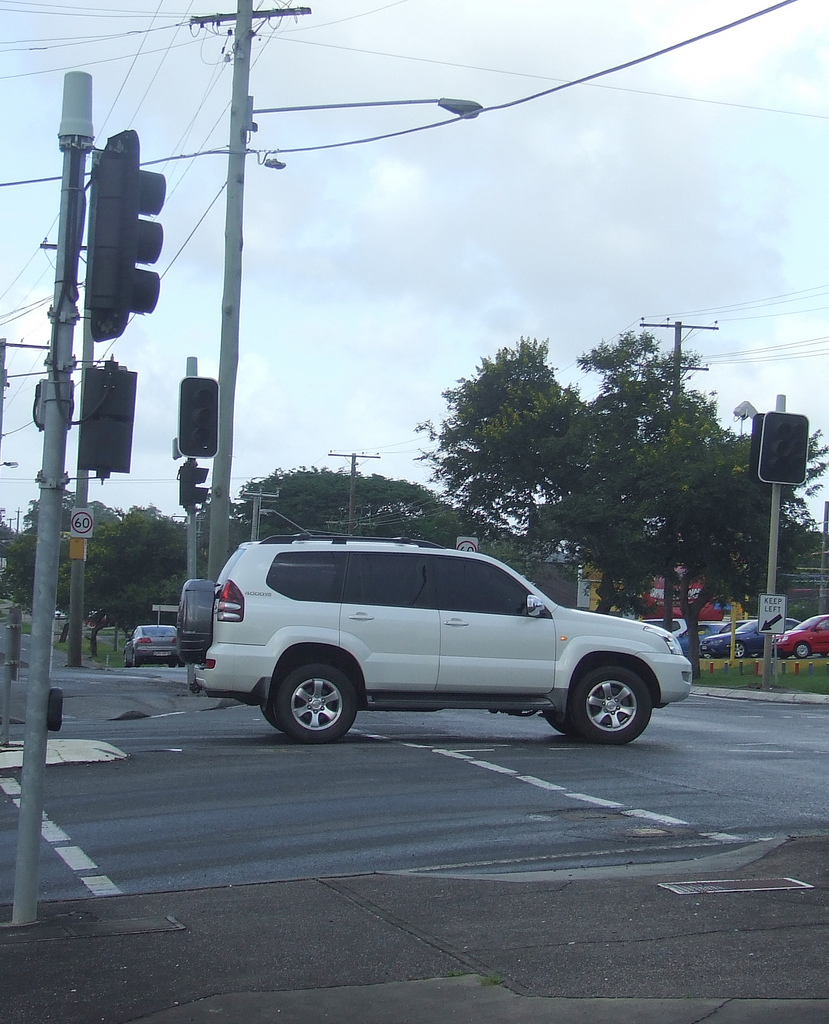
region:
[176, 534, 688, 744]
a white car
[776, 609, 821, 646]
a red car parked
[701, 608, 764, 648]
a blue car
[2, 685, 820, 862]
the street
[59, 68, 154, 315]
a street light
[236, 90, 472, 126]
a light pole hanging over the street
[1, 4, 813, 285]
wires from the power poles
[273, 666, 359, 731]
the tire on the white car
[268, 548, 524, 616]
windows of the car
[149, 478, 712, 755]
the car is white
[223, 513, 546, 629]
the windows are tinted black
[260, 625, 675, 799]
the wheels are black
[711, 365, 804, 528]
the traffic light is off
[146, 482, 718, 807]
the car is in the middle of the street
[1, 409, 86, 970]
the pole is grey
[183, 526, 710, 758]
SUV on the street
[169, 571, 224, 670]
spare tire on an SUV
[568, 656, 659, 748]
front tire on an suv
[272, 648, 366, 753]
back tire of an suv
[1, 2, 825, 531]
light blue colored sky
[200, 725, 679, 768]
shadow under a sky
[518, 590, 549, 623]
silver rear view mirror on an SUV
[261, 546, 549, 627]
tinted window on a white suv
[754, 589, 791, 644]
black and white sign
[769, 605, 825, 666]
red car in a parking lot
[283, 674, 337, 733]
Right rear wheel on the truck.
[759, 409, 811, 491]
Black traffic signal on the pole.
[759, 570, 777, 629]
Black and white arrow on the pole.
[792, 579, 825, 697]
Red car parked in the parking lot.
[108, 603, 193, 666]
Small grey car driving down the road.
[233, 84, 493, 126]
Light hanging from the pole over the cars.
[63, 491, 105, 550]
White traffic sign on the pole.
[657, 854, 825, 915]
Sewage drain in the sidewalk.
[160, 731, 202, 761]
White paper lying on the ground.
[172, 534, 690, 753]
vehicle near the road intersection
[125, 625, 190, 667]
vehicle near the road intersection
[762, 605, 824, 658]
vehicle near the road intersection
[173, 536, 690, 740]
a small white SUV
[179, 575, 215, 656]
tire rack on the back of a SUV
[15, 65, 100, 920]
metal pole in the sidewalk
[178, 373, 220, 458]
a traffic signal on a pole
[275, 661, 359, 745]
a tire on a suv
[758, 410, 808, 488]
a traffic light on a metal pole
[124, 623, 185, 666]
gray car on the street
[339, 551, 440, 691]
a door on a suv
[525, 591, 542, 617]
a side mirror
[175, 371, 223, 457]
a black street light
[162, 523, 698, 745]
a black and white suv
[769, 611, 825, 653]
the front of a red car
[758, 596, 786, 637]
a black and white sign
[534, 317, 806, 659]
a large green tree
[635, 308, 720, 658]
a tall brown light pole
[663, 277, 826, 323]
black electrical power lines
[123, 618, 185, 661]
the back of a car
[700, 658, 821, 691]
a small section of grass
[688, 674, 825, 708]
a small paved sidewalk